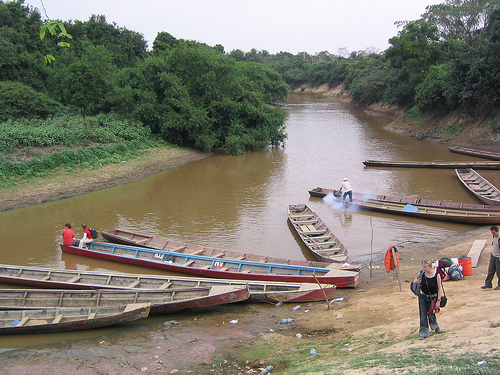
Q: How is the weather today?
A: It is cloudy.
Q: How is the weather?
A: It is cloudy.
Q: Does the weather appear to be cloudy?
A: Yes, it is cloudy.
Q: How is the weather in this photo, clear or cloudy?
A: It is cloudy.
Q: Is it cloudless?
A: No, it is cloudy.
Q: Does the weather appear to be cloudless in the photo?
A: No, it is cloudy.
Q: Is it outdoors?
A: Yes, it is outdoors.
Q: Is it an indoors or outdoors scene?
A: It is outdoors.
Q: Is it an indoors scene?
A: No, it is outdoors.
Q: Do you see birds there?
A: No, there are no birds.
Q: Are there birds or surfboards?
A: No, there are no birds or surfboards.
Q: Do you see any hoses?
A: No, there are no hoses.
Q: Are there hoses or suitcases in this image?
A: No, there are no hoses or suitcases.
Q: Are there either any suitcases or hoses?
A: No, there are no hoses or suitcases.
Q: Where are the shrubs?
A: The shrubs are on the shore.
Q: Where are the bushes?
A: The shrubs are on the shore.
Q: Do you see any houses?
A: No, there are no houses.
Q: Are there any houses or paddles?
A: No, there are no houses or paddles.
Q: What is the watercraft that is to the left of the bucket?
A: The watercraft is a canoe.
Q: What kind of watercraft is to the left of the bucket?
A: The watercraft is a canoe.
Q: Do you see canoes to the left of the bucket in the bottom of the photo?
A: Yes, there is a canoe to the left of the bucket.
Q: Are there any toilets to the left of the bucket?
A: No, there is a canoe to the left of the bucket.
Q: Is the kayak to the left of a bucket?
A: Yes, the kayak is to the left of a bucket.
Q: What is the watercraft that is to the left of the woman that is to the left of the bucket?
A: The watercraft is a canoe.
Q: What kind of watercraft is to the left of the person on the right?
A: The watercraft is a canoe.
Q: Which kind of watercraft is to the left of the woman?
A: The watercraft is a canoe.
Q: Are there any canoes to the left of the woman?
A: Yes, there is a canoe to the left of the woman.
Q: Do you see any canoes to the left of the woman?
A: Yes, there is a canoe to the left of the woman.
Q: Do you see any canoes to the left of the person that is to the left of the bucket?
A: Yes, there is a canoe to the left of the woman.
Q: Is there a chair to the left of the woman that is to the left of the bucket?
A: No, there is a canoe to the left of the woman.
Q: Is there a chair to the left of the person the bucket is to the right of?
A: No, there is a canoe to the left of the woman.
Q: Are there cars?
A: No, there are no cars.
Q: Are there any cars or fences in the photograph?
A: No, there are no cars or fences.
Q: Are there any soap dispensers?
A: No, there are no soap dispensers.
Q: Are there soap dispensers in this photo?
A: No, there are no soap dispensers.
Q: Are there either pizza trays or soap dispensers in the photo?
A: No, there are no soap dispensers or pizza trays.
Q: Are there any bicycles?
A: No, there are no bicycles.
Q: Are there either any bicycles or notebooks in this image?
A: No, there are no bicycles or notebooks.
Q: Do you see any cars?
A: No, there are no cars.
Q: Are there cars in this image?
A: No, there are no cars.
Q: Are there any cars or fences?
A: No, there are no cars or fences.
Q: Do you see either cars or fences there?
A: No, there are no cars or fences.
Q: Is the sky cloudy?
A: Yes, the sky is cloudy.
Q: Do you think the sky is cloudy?
A: Yes, the sky is cloudy.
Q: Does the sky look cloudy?
A: Yes, the sky is cloudy.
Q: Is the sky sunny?
A: No, the sky is cloudy.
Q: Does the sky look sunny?
A: No, the sky is cloudy.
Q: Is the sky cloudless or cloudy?
A: The sky is cloudy.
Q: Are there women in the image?
A: Yes, there is a woman.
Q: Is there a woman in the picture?
A: Yes, there is a woman.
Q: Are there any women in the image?
A: Yes, there is a woman.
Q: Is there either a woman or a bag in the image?
A: Yes, there is a woman.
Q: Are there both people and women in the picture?
A: Yes, there are both a woman and a person.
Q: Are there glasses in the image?
A: No, there are no glasses.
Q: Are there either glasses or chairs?
A: No, there are no glasses or chairs.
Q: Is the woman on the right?
A: Yes, the woman is on the right of the image.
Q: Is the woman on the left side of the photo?
A: No, the woman is on the right of the image.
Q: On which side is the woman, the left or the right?
A: The woman is on the right of the image.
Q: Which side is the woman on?
A: The woman is on the right of the image.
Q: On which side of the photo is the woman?
A: The woman is on the right of the image.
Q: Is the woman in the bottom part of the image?
A: Yes, the woman is in the bottom of the image.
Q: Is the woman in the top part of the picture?
A: No, the woman is in the bottom of the image.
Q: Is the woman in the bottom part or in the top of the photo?
A: The woman is in the bottom of the image.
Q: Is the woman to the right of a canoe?
A: Yes, the woman is to the right of a canoe.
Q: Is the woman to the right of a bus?
A: No, the woman is to the right of a canoe.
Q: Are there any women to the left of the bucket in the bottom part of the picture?
A: Yes, there is a woman to the left of the bucket.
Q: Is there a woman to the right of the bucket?
A: No, the woman is to the left of the bucket.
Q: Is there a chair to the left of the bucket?
A: No, there is a woman to the left of the bucket.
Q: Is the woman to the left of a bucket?
A: Yes, the woman is to the left of a bucket.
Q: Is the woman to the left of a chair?
A: No, the woman is to the left of a bucket.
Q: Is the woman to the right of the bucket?
A: No, the woman is to the left of the bucket.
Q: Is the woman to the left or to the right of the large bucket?
A: The woman is to the left of the bucket.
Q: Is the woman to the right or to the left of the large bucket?
A: The woman is to the left of the bucket.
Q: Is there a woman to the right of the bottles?
A: Yes, there is a woman to the right of the bottles.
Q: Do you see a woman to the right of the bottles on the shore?
A: Yes, there is a woman to the right of the bottles.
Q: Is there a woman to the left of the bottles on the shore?
A: No, the woman is to the right of the bottles.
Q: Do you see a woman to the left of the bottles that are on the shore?
A: No, the woman is to the right of the bottles.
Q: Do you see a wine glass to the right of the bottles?
A: No, there is a woman to the right of the bottles.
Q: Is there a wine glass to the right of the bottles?
A: No, there is a woman to the right of the bottles.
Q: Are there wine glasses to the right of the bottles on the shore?
A: No, there is a woman to the right of the bottles.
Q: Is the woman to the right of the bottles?
A: Yes, the woman is to the right of the bottles.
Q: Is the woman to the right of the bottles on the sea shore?
A: Yes, the woman is to the right of the bottles.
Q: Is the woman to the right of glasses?
A: No, the woman is to the right of the bottles.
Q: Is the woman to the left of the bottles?
A: No, the woman is to the right of the bottles.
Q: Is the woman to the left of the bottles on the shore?
A: No, the woman is to the right of the bottles.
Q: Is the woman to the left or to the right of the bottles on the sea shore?
A: The woman is to the right of the bottles.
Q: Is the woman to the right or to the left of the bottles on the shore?
A: The woman is to the right of the bottles.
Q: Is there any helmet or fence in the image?
A: No, there are no fences or helmets.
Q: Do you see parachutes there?
A: No, there are no parachutes.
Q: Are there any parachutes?
A: No, there are no parachutes.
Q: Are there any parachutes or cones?
A: No, there are no parachutes or cones.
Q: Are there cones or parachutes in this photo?
A: No, there are no parachutes or cones.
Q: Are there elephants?
A: No, there are no elephants.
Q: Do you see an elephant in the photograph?
A: No, there are no elephants.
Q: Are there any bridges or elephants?
A: No, there are no elephants or bridges.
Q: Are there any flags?
A: No, there are no flags.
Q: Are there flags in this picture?
A: No, there are no flags.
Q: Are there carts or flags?
A: No, there are no flags or carts.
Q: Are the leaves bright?
A: Yes, the leaves are bright.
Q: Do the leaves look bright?
A: Yes, the leaves are bright.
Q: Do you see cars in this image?
A: No, there are no cars.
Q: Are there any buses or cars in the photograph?
A: No, there are no cars or buses.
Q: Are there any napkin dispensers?
A: No, there are no napkin dispensers.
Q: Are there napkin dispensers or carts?
A: No, there are no napkin dispensers or carts.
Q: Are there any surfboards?
A: No, there are no surfboards.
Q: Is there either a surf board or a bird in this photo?
A: No, there are no surfboards or birds.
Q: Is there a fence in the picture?
A: No, there are no fences.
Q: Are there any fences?
A: No, there are no fences.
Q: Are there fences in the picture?
A: No, there are no fences.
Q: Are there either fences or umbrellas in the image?
A: No, there are no fences or umbrellas.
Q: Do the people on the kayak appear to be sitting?
A: Yes, the people are sitting.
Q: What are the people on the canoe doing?
A: The people are sitting.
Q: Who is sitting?
A: The people are sitting.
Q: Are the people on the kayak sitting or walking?
A: The people are sitting.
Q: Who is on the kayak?
A: The people are on the kayak.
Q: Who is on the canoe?
A: The people are on the kayak.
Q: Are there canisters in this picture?
A: No, there are no canisters.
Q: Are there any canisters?
A: No, there are no canisters.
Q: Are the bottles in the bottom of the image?
A: Yes, the bottles are in the bottom of the image.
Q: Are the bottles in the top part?
A: No, the bottles are in the bottom of the image.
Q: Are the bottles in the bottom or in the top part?
A: The bottles are in the bottom of the image.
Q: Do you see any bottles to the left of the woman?
A: Yes, there are bottles to the left of the woman.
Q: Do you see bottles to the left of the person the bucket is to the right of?
A: Yes, there are bottles to the left of the woman.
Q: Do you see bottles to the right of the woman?
A: No, the bottles are to the left of the woman.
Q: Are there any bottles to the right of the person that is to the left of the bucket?
A: No, the bottles are to the left of the woman.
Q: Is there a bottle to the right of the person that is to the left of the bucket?
A: No, the bottles are to the left of the woman.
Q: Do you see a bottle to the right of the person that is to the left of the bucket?
A: No, the bottles are to the left of the woman.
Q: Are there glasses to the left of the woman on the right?
A: No, there are bottles to the left of the woman.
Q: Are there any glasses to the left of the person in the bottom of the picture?
A: No, there are bottles to the left of the woman.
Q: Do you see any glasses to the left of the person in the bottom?
A: No, there are bottles to the left of the woman.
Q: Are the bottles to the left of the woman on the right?
A: Yes, the bottles are to the left of the woman.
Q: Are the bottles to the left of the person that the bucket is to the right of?
A: Yes, the bottles are to the left of the woman.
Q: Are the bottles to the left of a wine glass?
A: No, the bottles are to the left of the woman.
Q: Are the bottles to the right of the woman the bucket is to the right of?
A: No, the bottles are to the left of the woman.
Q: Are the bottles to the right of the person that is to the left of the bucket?
A: No, the bottles are to the left of the woman.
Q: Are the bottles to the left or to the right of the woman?
A: The bottles are to the left of the woman.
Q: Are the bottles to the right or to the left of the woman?
A: The bottles are to the left of the woman.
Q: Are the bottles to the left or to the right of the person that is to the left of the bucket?
A: The bottles are to the left of the woman.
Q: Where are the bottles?
A: The bottles are on the sea shore.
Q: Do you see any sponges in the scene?
A: No, there are no sponges.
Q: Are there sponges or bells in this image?
A: No, there are no sponges or bells.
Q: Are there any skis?
A: No, there are no skis.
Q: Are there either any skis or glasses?
A: No, there are no skis or glasses.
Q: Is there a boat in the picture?
A: Yes, there is a boat.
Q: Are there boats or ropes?
A: Yes, there is a boat.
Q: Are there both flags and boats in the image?
A: No, there is a boat but no flags.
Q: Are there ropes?
A: No, there are no ropes.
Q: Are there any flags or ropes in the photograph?
A: No, there are no ropes or flags.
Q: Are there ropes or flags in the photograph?
A: No, there are no ropes or flags.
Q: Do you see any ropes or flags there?
A: No, there are no ropes or flags.